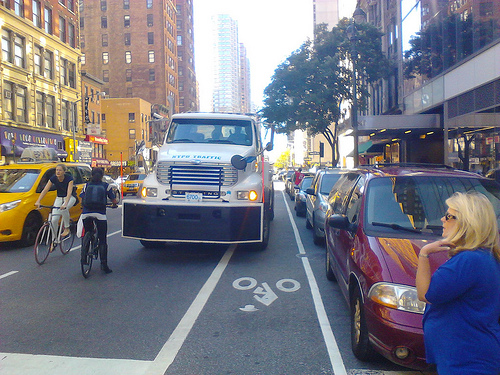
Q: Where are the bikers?
A: On the road.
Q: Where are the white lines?
A: On the road.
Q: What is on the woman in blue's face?
A: Glasses.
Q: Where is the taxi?
A: Left of biker.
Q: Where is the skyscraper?
A: In the distance.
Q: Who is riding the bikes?
A: The women.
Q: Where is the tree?
A: By the mirrored building.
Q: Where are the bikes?
A: In the street.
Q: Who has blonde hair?
A: The woman.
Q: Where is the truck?
A: In the street.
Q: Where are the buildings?
A: Surrounding the sidewalk.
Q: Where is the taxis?
A: Left side of the street.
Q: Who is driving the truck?
A: The man.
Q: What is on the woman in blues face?
A: Glasses.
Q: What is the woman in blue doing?
A: Standing.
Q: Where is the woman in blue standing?
A: Side of the street.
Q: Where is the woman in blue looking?
A: Straight ahead.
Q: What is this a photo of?
A: An urban street.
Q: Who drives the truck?
A: The truck driver.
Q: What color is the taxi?
A: Yellow.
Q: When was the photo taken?
A: Daytime.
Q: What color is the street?
A: Black.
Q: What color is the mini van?
A: Red.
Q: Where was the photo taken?
A: On the street.